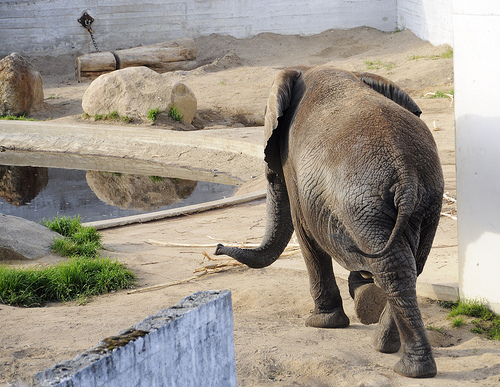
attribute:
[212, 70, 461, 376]
elephant — lumbering, walking, gray, dry, grey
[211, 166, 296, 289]
trunk — long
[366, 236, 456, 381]
leg — grey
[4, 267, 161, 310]
grass — green, patch of, present, here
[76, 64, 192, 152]
rock — reflecting, large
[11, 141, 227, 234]
water — for an animal in zoo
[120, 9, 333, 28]
wall — white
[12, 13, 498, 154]
building — here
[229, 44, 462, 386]
animal — here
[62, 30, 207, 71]
tree trunk — chained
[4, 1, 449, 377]
pen — animals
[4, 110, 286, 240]
pool — little